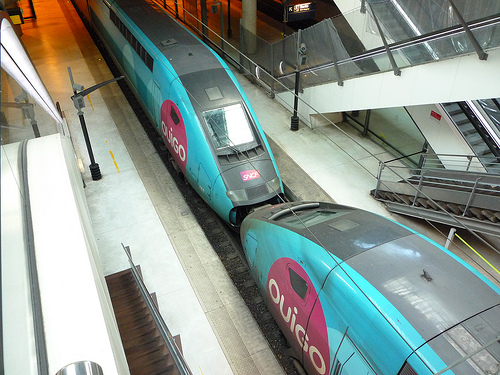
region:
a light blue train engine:
[73, 0, 285, 230]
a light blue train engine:
[238, 200, 499, 372]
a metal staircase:
[370, 150, 499, 235]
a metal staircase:
[104, 244, 195, 374]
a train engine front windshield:
[202, 101, 254, 150]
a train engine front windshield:
[277, 201, 335, 227]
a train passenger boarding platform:
[15, 0, 282, 374]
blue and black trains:
[140, 35, 415, 331]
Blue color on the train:
[334, 276, 371, 338]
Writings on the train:
[151, 108, 184, 156]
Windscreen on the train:
[205, 107, 252, 147]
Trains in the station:
[155, 78, 360, 288]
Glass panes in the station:
[292, 32, 377, 67]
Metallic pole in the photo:
[290, 80, 304, 123]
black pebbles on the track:
[225, 252, 244, 282]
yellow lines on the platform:
[95, 140, 125, 180]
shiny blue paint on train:
[327, 280, 373, 320]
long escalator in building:
[369, 14, 484, 169]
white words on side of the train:
[262, 277, 328, 360]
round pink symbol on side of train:
[261, 246, 336, 331]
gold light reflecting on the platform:
[23, 2, 93, 47]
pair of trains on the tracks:
[141, 38, 427, 328]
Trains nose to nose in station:
[24, 11, 486, 369]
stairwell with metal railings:
[360, 137, 497, 231]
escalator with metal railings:
[351, 4, 499, 186]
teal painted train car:
[91, 11, 311, 220]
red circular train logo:
[148, 96, 213, 177]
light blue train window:
[199, 91, 271, 176]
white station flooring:
[90, 164, 235, 374]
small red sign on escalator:
[417, 101, 452, 137]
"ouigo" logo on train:
[257, 259, 337, 374]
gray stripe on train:
[129, 14, 295, 198]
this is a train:
[83, 0, 280, 202]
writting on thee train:
[254, 259, 343, 374]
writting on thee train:
[159, 88, 199, 174]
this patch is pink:
[258, 253, 333, 373]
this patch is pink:
[148, 97, 194, 171]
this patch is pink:
[240, 156, 272, 188]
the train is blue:
[249, 188, 477, 373]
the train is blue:
[97, 0, 285, 213]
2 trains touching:
[176, 99, 358, 308]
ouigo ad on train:
[264, 252, 339, 368]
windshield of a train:
[201, 106, 259, 153]